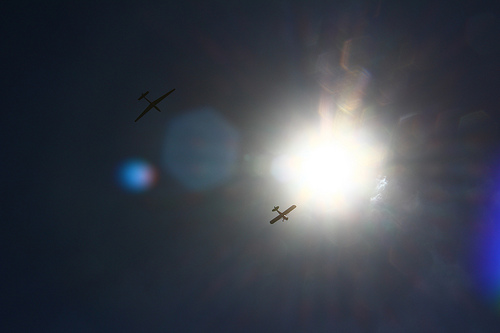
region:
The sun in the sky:
[277, 123, 374, 210]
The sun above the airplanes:
[280, 122, 372, 205]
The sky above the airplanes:
[1, 1, 497, 331]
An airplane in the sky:
[266, 202, 296, 222]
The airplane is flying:
[268, 203, 295, 223]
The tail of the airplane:
[270, 200, 280, 211]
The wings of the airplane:
[268, 203, 295, 221]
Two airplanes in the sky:
[132, 88, 295, 225]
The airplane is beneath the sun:
[270, 205, 295, 223]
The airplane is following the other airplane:
[134, 87, 173, 117]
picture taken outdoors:
[11, 10, 489, 331]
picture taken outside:
[8, 5, 492, 325]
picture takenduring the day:
[10, 8, 447, 328]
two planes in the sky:
[21, 28, 345, 246]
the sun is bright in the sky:
[71, 54, 405, 269]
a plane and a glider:
[74, 33, 362, 278]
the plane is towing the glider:
[82, 51, 369, 258]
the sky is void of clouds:
[11, 13, 491, 326]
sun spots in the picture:
[76, 55, 416, 235]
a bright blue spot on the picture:
[467, 137, 491, 298]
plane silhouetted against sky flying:
[265, 197, 296, 224]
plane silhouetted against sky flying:
[125, 80, 180, 127]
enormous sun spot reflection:
[222, 48, 454, 289]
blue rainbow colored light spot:
[111, 153, 163, 200]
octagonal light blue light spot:
[162, 113, 244, 211]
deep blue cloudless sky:
[8, 0, 497, 327]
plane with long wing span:
[128, 80, 180, 125]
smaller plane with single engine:
[267, 198, 299, 228]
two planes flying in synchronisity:
[131, 75, 303, 247]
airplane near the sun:
[259, 191, 301, 233]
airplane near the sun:
[136, 86, 190, 142]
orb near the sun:
[115, 157, 167, 212]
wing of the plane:
[286, 203, 300, 216]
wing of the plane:
[270, 217, 280, 222]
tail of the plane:
[271, 206, 276, 214]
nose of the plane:
[281, 215, 288, 219]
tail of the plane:
[135, 88, 152, 102]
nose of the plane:
[156, 106, 164, 119]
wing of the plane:
[164, 84, 180, 97]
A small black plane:
[252, 198, 313, 227]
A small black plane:
[125, 94, 182, 124]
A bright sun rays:
[270, 109, 403, 217]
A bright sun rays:
[196, 226, 263, 300]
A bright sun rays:
[357, 226, 414, 311]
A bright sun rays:
[418, 103, 461, 203]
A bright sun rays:
[287, 48, 434, 94]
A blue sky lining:
[11, 186, 69, 287]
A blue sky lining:
[11, 76, 68, 167]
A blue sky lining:
[27, 273, 112, 328]